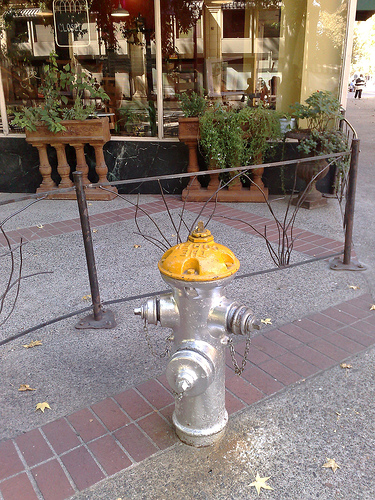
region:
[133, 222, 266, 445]
silver and yellow fire hydrant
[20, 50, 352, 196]
decorative planters near store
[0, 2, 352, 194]
store with large glass windows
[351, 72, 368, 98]
person wearing book bag walking down street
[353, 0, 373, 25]
green awning affixed to store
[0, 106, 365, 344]
decorative metal railing enclosing store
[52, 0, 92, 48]
sign in the window of store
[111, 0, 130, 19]
light hanging from ceiling inside store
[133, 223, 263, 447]
fire hydrant cemented to sidewalk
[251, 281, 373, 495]
yellow leaves laying on ground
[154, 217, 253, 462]
this is a hydrant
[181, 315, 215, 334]
the hydrant is shinny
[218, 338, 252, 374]
this is a chain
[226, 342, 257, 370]
the chain is metallic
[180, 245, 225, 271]
the top is yellow in color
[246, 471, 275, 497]
this is a leaf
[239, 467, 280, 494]
the leaf is star shaped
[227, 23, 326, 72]
this is a building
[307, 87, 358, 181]
this is a tree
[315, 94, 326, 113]
the leaves are green in color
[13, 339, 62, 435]
leaves on the ground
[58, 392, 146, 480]
red bricks on the sidewalk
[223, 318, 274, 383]
chain on fire hydrant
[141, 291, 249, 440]
silver fire hydrant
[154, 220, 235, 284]
yellow lid on top of silver hydrant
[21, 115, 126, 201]
brown brass flower holder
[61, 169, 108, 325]
black iron post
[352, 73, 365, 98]
person standing on the street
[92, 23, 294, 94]
large apartment building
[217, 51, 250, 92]
windows in apartment building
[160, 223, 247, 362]
Silver fire hydrant with gold top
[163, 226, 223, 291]
Gold cover on a fire hydrant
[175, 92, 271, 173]
Fire pots on a pillar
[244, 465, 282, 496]
Leaf on the ground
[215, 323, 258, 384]
Chain on a fire hydrant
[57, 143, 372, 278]
Two metal poles on the sidewalk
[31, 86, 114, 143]
plants in the flower pot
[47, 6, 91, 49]
closed sign in the window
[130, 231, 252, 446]
fire hydrant on the sidewalk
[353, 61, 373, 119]
person walking on the street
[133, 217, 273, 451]
a fire hydrant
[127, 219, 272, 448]
the bottom of the fire hydrant is silver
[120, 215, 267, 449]
the top of the fire hydrant is yellow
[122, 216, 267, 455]
a silver and yellow fire hydrant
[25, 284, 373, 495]
a few leaves are scattered on the ground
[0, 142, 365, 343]
a metal fence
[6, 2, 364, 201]
a store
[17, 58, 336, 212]
potted plants along the side of the store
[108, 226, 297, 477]
the fire hydrant is on the sidewalk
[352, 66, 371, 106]
a person walking on the sidewalk